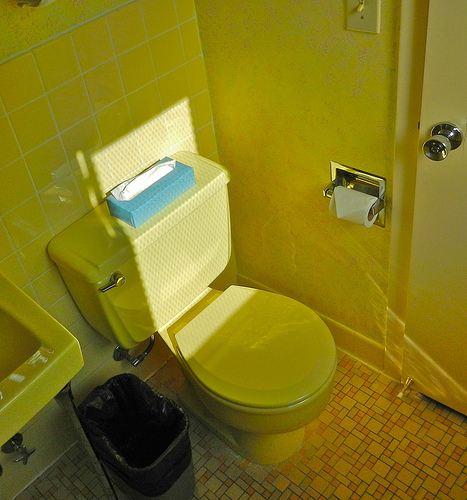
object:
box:
[105, 156, 198, 228]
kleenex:
[109, 158, 176, 204]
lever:
[100, 270, 125, 292]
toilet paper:
[329, 185, 380, 228]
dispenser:
[321, 159, 388, 228]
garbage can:
[73, 371, 196, 498]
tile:
[333, 457, 354, 477]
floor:
[1, 288, 465, 499]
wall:
[1, 2, 238, 499]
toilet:
[46, 152, 339, 467]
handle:
[422, 122, 465, 163]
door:
[401, 0, 467, 423]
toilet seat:
[172, 283, 337, 436]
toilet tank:
[46, 148, 233, 350]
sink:
[1, 270, 86, 451]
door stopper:
[396, 377, 413, 400]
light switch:
[343, 0, 381, 35]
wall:
[196, 2, 396, 374]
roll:
[328, 185, 379, 229]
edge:
[0, 283, 85, 371]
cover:
[172, 284, 339, 412]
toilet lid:
[173, 285, 339, 411]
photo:
[1, 2, 466, 498]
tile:
[82, 54, 127, 115]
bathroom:
[0, 2, 466, 500]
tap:
[1, 431, 37, 466]